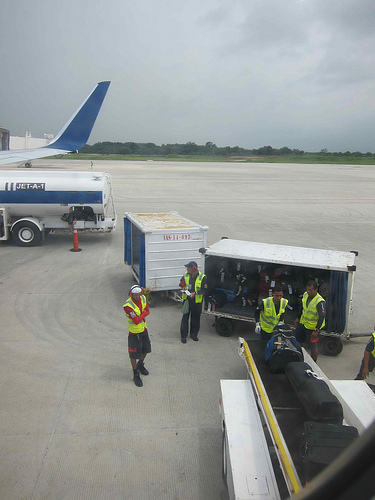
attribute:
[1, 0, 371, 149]
sky — gray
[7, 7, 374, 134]
clouds — dark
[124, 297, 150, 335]
man — standing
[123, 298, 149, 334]
clothing — reflective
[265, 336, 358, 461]
bags — dark, tagged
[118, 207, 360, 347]
baggage trail — white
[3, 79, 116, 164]
airliner — sitting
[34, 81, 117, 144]
wing tip — white, blue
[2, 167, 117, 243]
fuel tanker — blue, white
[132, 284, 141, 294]
cap — white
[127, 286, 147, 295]
cap — white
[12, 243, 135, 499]
concrete — smooth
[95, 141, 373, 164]
bushes — green, thick, lush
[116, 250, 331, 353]
people — loading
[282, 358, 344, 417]
luggage — long, black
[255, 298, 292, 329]
vest — yellow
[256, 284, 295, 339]
man — wearing, standing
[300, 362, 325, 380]
tag — white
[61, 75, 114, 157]
plane's tail — blue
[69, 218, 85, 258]
cone — orange, white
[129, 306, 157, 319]
man's arms — folded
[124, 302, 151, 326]
employee's arms — folded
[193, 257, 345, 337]
cart — filled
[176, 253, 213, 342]
man — standing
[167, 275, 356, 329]
vests — yellow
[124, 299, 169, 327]
shirt — red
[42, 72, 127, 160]
tail — blue